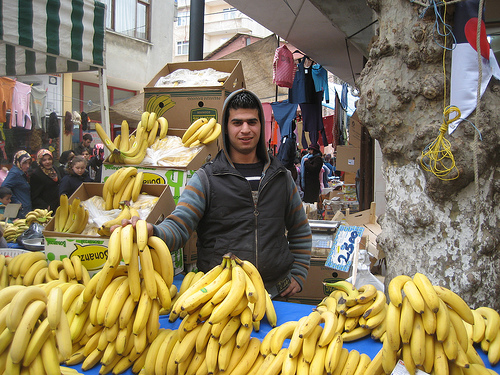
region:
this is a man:
[178, 87, 288, 250]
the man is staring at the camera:
[207, 91, 277, 250]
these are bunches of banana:
[160, 245, 260, 372]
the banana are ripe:
[170, 248, 273, 373]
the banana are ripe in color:
[166, 253, 267, 365]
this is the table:
[279, 301, 300, 316]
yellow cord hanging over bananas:
[417, 1, 467, 186]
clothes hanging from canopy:
[271, 35, 351, 136]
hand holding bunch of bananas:
[102, 209, 179, 301]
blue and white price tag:
[321, 216, 366, 273]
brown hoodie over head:
[216, 82, 278, 168]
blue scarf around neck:
[299, 147, 321, 191]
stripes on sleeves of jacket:
[147, 168, 312, 288]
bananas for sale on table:
[7, 253, 497, 373]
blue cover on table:
[257, 293, 378, 353]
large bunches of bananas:
[21, 257, 489, 369]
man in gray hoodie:
[210, 104, 291, 279]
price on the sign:
[318, 200, 382, 288]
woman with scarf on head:
[37, 140, 58, 186]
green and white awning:
[0, 7, 133, 57]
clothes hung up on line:
[1, 78, 66, 133]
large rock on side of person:
[368, 17, 498, 293]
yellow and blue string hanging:
[417, 0, 457, 189]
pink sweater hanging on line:
[262, 43, 297, 100]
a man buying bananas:
[142, 78, 318, 298]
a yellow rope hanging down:
[415, 0, 462, 181]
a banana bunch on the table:
[169, 248, 278, 351]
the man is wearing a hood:
[202, 85, 272, 176]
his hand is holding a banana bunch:
[105, 215, 173, 305]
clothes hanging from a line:
[3, 73, 53, 136]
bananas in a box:
[80, 104, 227, 181]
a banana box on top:
[142, 51, 249, 131]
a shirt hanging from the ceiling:
[265, 38, 299, 95]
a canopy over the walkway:
[0, 0, 106, 96]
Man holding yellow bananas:
[103, 210, 183, 290]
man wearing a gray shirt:
[164, 142, 296, 280]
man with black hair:
[221, 90, 261, 111]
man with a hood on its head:
[206, 76, 271, 156]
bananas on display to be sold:
[60, 255, 352, 370]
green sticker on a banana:
[196, 281, 211, 299]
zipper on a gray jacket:
[249, 201, 264, 218]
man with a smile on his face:
[234, 128, 254, 143]